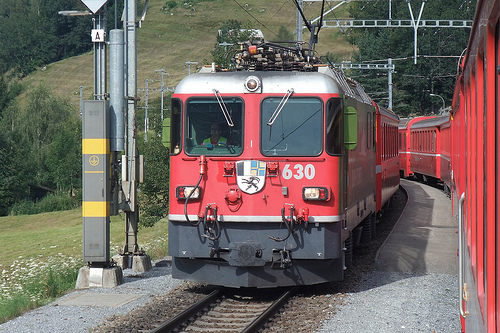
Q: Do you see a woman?
A: No, there are no women.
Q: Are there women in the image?
A: No, there are no women.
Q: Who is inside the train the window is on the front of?
A: The driver is inside the train.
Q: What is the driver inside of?
A: The driver is inside the train.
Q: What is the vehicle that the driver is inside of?
A: The vehicle is a train.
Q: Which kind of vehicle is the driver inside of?
A: The driver is inside the train.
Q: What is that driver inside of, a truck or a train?
A: The driver is inside a train.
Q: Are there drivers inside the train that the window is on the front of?
A: Yes, there is a driver inside the train.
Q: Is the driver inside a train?
A: Yes, the driver is inside a train.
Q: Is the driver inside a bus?
A: No, the driver is inside a train.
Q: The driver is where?
A: The driver is in the train.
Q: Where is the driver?
A: The driver is in the train.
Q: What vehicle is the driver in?
A: The driver is in the train.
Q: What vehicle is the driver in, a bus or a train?
A: The driver is in a train.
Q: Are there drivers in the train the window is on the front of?
A: Yes, there is a driver in the train.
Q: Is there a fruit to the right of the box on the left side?
A: No, there is a driver to the right of the box.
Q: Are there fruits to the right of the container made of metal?
A: No, there is a driver to the right of the box.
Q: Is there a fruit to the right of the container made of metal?
A: No, there is a driver to the right of the box.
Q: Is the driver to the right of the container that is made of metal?
A: Yes, the driver is to the right of the box.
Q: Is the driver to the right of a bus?
A: No, the driver is to the right of the box.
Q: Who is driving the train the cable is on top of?
A: The driver is driving the train.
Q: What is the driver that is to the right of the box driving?
A: The driver is driving the train.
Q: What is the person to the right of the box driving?
A: The driver is driving the train.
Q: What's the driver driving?
A: The driver is driving the train.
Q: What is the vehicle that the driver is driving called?
A: The vehicle is a train.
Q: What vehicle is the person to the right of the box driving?
A: The driver is driving the train.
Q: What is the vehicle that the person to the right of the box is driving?
A: The vehicle is a train.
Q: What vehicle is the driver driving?
A: The driver is driving the train.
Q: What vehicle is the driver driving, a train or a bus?
A: The driver is driving a train.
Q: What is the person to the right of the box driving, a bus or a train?
A: The driver is driving a train.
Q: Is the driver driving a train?
A: Yes, the driver is driving a train.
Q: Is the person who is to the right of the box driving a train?
A: Yes, the driver is driving a train.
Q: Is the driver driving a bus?
A: No, the driver is driving a train.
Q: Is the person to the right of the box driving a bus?
A: No, the driver is driving a train.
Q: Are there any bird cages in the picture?
A: No, there are no bird cages.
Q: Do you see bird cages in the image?
A: No, there are no bird cages.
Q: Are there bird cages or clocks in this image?
A: No, there are no bird cages or clocks.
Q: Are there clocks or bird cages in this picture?
A: No, there are no bird cages or clocks.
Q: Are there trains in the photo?
A: Yes, there is a train.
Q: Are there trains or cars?
A: Yes, there is a train.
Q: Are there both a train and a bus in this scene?
A: No, there is a train but no buses.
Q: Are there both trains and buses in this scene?
A: No, there is a train but no buses.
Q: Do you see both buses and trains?
A: No, there is a train but no buses.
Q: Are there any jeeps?
A: No, there are no jeeps.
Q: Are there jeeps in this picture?
A: No, there are no jeeps.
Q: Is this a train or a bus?
A: This is a train.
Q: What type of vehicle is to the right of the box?
A: The vehicle is a train.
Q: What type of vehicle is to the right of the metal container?
A: The vehicle is a train.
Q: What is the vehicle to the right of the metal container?
A: The vehicle is a train.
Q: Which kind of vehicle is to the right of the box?
A: The vehicle is a train.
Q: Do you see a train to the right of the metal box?
A: Yes, there is a train to the right of the box.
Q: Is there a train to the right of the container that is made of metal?
A: Yes, there is a train to the right of the box.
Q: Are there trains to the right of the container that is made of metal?
A: Yes, there is a train to the right of the box.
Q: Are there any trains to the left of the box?
A: No, the train is to the right of the box.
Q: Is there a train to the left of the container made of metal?
A: No, the train is to the right of the box.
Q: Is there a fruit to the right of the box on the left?
A: No, there is a train to the right of the box.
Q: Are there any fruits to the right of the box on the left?
A: No, there is a train to the right of the box.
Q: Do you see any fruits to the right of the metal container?
A: No, there is a train to the right of the box.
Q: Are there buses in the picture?
A: No, there are no buses.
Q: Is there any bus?
A: No, there are no buses.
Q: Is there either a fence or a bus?
A: No, there are no buses or fences.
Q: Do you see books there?
A: No, there are no books.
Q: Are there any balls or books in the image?
A: No, there are no books or balls.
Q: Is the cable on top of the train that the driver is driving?
A: Yes, the cable is on top of the train.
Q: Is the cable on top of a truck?
A: No, the cable is on top of the train.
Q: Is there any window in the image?
A: Yes, there is a window.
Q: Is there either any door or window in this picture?
A: Yes, there is a window.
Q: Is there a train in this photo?
A: Yes, there is a train.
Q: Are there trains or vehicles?
A: Yes, there is a train.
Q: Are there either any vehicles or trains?
A: Yes, there is a train.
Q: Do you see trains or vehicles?
A: Yes, there is a train.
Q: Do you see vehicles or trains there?
A: Yes, there is a train.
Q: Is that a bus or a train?
A: That is a train.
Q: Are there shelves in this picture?
A: No, there are no shelves.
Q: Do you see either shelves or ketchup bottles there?
A: No, there are no shelves or ketchup bottles.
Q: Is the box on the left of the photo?
A: Yes, the box is on the left of the image.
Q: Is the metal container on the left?
A: Yes, the box is on the left of the image.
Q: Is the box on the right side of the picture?
A: No, the box is on the left of the image.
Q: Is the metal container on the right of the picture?
A: No, the box is on the left of the image.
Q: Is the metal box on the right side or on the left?
A: The box is on the left of the image.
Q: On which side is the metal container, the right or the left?
A: The box is on the left of the image.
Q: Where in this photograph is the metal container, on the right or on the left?
A: The box is on the left of the image.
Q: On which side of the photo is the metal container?
A: The box is on the left of the image.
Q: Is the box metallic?
A: Yes, the box is metallic.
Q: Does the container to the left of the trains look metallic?
A: Yes, the box is metallic.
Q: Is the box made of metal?
A: Yes, the box is made of metal.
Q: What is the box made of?
A: The box is made of metal.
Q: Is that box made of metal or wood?
A: The box is made of metal.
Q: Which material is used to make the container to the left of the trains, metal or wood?
A: The box is made of metal.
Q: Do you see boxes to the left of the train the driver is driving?
A: Yes, there is a box to the left of the train.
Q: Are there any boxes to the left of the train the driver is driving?
A: Yes, there is a box to the left of the train.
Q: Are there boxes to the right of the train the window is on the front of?
A: No, the box is to the left of the train.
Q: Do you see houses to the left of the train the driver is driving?
A: No, there is a box to the left of the train.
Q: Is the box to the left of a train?
A: Yes, the box is to the left of a train.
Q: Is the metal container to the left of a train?
A: Yes, the box is to the left of a train.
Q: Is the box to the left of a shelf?
A: No, the box is to the left of a train.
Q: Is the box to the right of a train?
A: No, the box is to the left of a train.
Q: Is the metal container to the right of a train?
A: No, the box is to the left of a train.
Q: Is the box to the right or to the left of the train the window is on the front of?
A: The box is to the left of the train.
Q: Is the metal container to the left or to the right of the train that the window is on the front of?
A: The box is to the left of the train.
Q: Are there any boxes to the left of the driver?
A: Yes, there is a box to the left of the driver.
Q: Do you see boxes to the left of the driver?
A: Yes, there is a box to the left of the driver.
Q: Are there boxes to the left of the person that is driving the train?
A: Yes, there is a box to the left of the driver.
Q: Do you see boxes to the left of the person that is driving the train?
A: Yes, there is a box to the left of the driver.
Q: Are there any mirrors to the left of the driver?
A: No, there is a box to the left of the driver.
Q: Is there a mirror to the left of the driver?
A: No, there is a box to the left of the driver.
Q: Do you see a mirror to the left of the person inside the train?
A: No, there is a box to the left of the driver.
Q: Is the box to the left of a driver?
A: Yes, the box is to the left of a driver.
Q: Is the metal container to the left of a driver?
A: Yes, the box is to the left of a driver.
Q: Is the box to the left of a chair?
A: No, the box is to the left of a driver.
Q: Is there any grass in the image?
A: Yes, there is grass.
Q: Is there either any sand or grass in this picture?
A: Yes, there is grass.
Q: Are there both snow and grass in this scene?
A: No, there is grass but no snow.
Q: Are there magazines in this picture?
A: No, there are no magazines.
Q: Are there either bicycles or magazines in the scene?
A: No, there are no magazines or bicycles.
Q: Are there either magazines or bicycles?
A: No, there are no magazines or bicycles.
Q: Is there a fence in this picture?
A: No, there are no fences.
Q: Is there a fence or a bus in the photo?
A: No, there are no fences or buses.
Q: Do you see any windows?
A: Yes, there is a window.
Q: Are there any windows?
A: Yes, there is a window.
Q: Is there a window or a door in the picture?
A: Yes, there is a window.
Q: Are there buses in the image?
A: No, there are no buses.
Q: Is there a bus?
A: No, there are no buses.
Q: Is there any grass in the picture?
A: Yes, there is grass.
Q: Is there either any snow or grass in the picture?
A: Yes, there is grass.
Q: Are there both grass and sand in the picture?
A: No, there is grass but no sand.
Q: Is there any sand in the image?
A: No, there is no sand.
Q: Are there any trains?
A: Yes, there are trains.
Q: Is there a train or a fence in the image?
A: Yes, there are trains.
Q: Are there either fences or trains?
A: Yes, there are trains.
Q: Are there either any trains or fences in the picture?
A: Yes, there are trains.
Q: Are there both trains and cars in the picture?
A: No, there are trains but no cars.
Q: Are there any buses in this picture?
A: No, there are no buses.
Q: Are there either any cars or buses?
A: No, there are no buses or cars.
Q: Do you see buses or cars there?
A: No, there are no buses or cars.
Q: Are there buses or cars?
A: No, there are no buses or cars.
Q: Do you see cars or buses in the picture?
A: No, there are no buses or cars.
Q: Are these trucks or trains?
A: These are trains.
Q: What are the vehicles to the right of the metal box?
A: The vehicles are trains.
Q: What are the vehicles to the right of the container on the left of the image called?
A: The vehicles are trains.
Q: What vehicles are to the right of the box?
A: The vehicles are trains.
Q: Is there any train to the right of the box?
A: Yes, there are trains to the right of the box.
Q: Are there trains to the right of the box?
A: Yes, there are trains to the right of the box.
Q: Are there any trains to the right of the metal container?
A: Yes, there are trains to the right of the box.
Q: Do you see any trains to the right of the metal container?
A: Yes, there are trains to the right of the box.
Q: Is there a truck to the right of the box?
A: No, there are trains to the right of the box.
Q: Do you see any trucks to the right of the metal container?
A: No, there are trains to the right of the box.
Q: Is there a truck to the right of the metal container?
A: No, there are trains to the right of the box.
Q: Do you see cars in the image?
A: No, there are no cars.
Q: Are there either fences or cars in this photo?
A: No, there are no cars or fences.